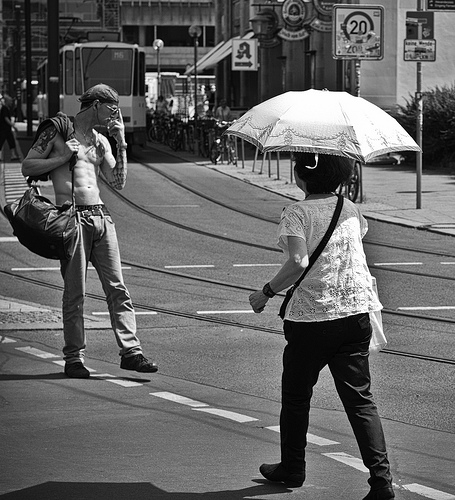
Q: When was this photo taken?
A: During the daytime.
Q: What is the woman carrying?
A: An umbrella.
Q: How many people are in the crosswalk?
A: Two.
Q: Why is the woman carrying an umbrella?
A: To keep the sun off of her.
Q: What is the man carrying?
A: A bag.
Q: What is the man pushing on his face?
A: Sunglasses.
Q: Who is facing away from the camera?
A: The woman with the umbrella.